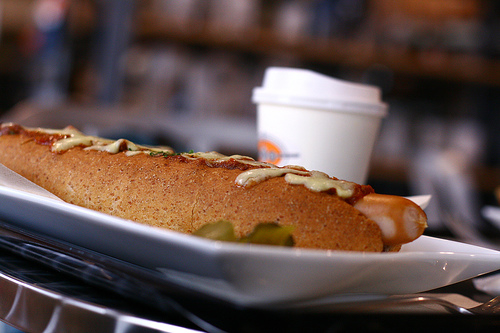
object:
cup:
[249, 61, 391, 190]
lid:
[249, 62, 393, 122]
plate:
[0, 166, 500, 310]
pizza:
[2, 109, 438, 255]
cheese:
[2, 117, 366, 203]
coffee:
[241, 57, 400, 191]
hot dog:
[346, 186, 434, 243]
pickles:
[193, 212, 299, 251]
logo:
[247, 127, 303, 168]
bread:
[0, 115, 438, 268]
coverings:
[0, 112, 370, 205]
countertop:
[0, 232, 500, 333]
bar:
[1, 0, 499, 332]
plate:
[268, 290, 500, 316]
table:
[0, 143, 499, 332]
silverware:
[267, 288, 496, 325]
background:
[1, 0, 500, 248]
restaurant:
[1, 0, 500, 331]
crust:
[174, 155, 237, 187]